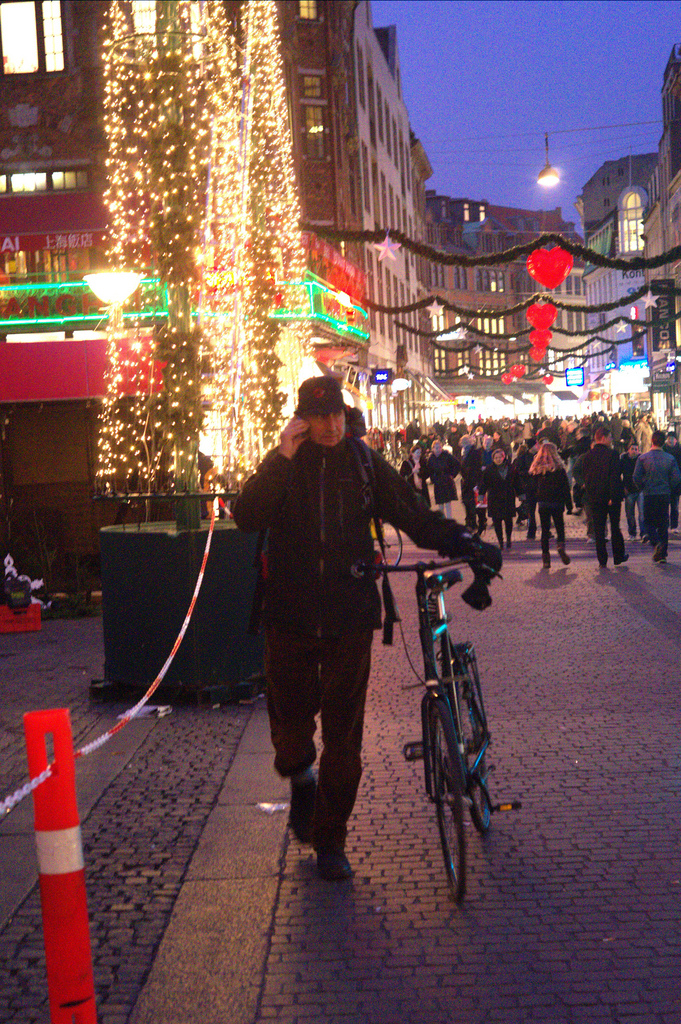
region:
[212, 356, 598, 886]
Man walking down street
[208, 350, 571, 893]
Man in black sweater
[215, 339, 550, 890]
Man standing near Christmas lights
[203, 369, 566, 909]
Man having conversation on phone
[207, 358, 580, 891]
Man with arm on bike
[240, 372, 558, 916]
Man on phone in a street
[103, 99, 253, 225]
lights on the tree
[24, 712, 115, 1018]
an orange pole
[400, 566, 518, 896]
a bike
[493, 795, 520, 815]
a peddle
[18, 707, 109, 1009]
an orange and white cone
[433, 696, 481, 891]
a tire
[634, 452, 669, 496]
a blue jacket a man is wearing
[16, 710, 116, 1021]
orange pole standing up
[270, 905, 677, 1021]
brick pavement on the ground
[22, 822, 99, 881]
white stripe on pole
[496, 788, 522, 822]
pedal on the bike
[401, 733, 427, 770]
pedal on the bike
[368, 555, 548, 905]
a blue bike on ground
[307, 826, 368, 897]
left foot of the person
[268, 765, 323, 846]
right foot of the person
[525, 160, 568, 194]
street light hanging in air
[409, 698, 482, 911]
front tire on the bike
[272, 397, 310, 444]
man has phone in his hand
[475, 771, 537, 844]
pedal has orange reflector on it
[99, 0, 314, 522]
christmas tree has lights on it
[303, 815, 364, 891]
man is wearing shoes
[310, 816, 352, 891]
shoes are black in color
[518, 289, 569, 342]
red balls are hanging in the air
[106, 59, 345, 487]
christmas lights on a building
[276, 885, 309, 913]
brick in a sidewalk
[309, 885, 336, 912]
brick in a sidewalk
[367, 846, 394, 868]
brick in a sidewalk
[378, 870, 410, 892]
brick in a sidewalk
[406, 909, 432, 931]
brick in a sidewalk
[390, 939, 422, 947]
brick in a sidewalk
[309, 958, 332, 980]
brick in a sidewalk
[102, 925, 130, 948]
brick in a sidewalk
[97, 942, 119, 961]
brick in a sidewalk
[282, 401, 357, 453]
man talking on a cellphone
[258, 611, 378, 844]
man wearing brown pants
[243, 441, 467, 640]
man wearing a brown jacket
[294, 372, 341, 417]
man wearing a black hat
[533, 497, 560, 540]
woman wearing blue jeans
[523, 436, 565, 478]
woman with blonde hair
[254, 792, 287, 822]
plastic wrapper on the ground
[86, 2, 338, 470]
lights hanging from the building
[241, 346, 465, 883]
person on a sidewalk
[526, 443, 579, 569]
person on a sidewalk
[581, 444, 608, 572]
person on a sidewalk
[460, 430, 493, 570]
person on a sidewalk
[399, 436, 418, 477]
person on a sidewalk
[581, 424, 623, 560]
person on a sidewalk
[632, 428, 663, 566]
person on a sidewalk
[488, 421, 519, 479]
person on a sidewalk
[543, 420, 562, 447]
person on a sidewalk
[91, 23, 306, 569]
white lights behind man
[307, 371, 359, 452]
man has black hat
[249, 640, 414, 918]
man has brown pants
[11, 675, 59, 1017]
orange and white post